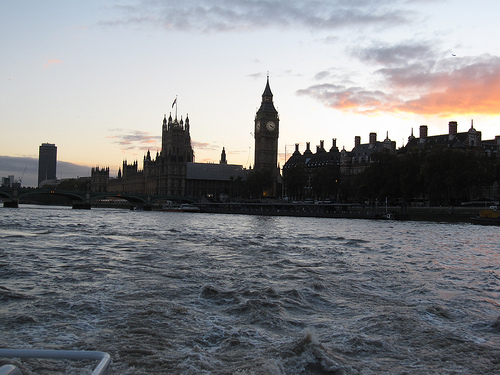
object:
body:
[0, 203, 499, 373]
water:
[0, 202, 499, 374]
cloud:
[296, 36, 499, 115]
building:
[38, 143, 58, 189]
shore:
[137, 186, 498, 226]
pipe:
[0, 346, 109, 374]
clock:
[265, 120, 276, 131]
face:
[265, 120, 278, 134]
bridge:
[0, 186, 149, 210]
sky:
[1, 1, 498, 188]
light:
[262, 191, 267, 196]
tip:
[265, 72, 272, 83]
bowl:
[481, 207, 499, 222]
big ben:
[252, 72, 279, 202]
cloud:
[116, 127, 215, 157]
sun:
[84, 161, 120, 174]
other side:
[1, 0, 500, 205]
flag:
[171, 94, 178, 120]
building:
[90, 75, 280, 201]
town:
[0, 69, 499, 208]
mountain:
[0, 155, 94, 197]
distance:
[0, 119, 500, 295]